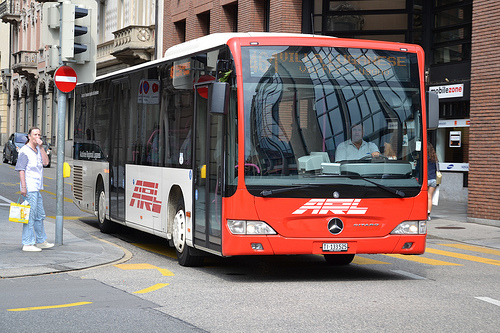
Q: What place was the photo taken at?
A: It was taken at the street.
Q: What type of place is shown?
A: It is a street.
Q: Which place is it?
A: It is a street.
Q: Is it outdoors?
A: Yes, it is outdoors.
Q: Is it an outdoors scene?
A: Yes, it is outdoors.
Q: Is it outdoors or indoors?
A: It is outdoors.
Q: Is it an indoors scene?
A: No, it is outdoors.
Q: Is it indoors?
A: No, it is outdoors.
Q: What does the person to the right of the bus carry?
A: The person carries a bag.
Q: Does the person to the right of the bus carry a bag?
A: Yes, the person carries a bag.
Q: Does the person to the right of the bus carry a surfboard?
A: No, the person carries a bag.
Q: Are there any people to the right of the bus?
A: Yes, there is a person to the right of the bus.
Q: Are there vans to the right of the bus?
A: No, there is a person to the right of the bus.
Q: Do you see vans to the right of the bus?
A: No, there is a person to the right of the bus.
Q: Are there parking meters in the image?
A: No, there are no parking meters.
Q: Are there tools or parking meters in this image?
A: No, there are no parking meters or tools.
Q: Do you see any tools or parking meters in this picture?
A: No, there are no parking meters or tools.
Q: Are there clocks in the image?
A: No, there are no clocks.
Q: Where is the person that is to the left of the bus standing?
A: The person is standing at the sidewalk.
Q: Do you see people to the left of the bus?
A: Yes, there is a person to the left of the bus.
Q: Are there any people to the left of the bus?
A: Yes, there is a person to the left of the bus.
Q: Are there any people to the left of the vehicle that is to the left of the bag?
A: Yes, there is a person to the left of the bus.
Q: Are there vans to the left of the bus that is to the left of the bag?
A: No, there is a person to the left of the bus.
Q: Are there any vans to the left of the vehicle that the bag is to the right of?
A: No, there is a person to the left of the bus.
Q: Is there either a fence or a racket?
A: No, there are no fences or rackets.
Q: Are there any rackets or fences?
A: No, there are no fences or rackets.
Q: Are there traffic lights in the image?
A: Yes, there is a traffic light.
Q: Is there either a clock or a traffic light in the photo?
A: Yes, there is a traffic light.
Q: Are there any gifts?
A: No, there are no gifts.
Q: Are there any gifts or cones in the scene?
A: No, there are no gifts or cones.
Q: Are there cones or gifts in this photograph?
A: No, there are no gifts or cones.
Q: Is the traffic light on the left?
A: Yes, the traffic light is on the left of the image.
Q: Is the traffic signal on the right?
A: No, the traffic signal is on the left of the image.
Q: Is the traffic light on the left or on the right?
A: The traffic light is on the left of the image.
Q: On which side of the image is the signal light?
A: The signal light is on the left of the image.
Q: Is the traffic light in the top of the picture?
A: Yes, the traffic light is in the top of the image.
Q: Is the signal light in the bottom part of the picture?
A: No, the signal light is in the top of the image.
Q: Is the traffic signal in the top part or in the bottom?
A: The traffic signal is in the top of the image.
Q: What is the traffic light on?
A: The traffic light is on the pole.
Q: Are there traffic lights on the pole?
A: Yes, there is a traffic light on the pole.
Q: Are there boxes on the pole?
A: No, there is a traffic light on the pole.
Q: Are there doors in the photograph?
A: Yes, there is a door.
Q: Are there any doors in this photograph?
A: Yes, there is a door.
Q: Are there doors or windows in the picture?
A: Yes, there is a door.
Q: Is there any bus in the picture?
A: Yes, there is a bus.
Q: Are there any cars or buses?
A: Yes, there is a bus.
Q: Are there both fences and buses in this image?
A: No, there is a bus but no fences.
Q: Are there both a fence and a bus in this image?
A: No, there is a bus but no fences.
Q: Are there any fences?
A: No, there are no fences.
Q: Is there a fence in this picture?
A: No, there are no fences.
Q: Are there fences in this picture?
A: No, there are no fences.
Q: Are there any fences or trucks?
A: No, there are no fences or trucks.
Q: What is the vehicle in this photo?
A: The vehicle is a bus.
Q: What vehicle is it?
A: The vehicle is a bus.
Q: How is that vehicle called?
A: This is a bus.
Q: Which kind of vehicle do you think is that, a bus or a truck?
A: This is a bus.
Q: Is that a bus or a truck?
A: That is a bus.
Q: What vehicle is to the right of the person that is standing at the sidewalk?
A: The vehicle is a bus.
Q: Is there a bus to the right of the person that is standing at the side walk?
A: Yes, there is a bus to the right of the person.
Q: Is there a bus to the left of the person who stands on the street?
A: No, the bus is to the right of the person.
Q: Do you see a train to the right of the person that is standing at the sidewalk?
A: No, there is a bus to the right of the person.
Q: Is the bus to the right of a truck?
A: No, the bus is to the right of a person.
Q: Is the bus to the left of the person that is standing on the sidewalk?
A: No, the bus is to the right of the person.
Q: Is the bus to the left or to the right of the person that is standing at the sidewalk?
A: The bus is to the right of the person.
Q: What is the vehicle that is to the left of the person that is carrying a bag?
A: The vehicle is a bus.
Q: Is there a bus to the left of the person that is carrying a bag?
A: Yes, there is a bus to the left of the person.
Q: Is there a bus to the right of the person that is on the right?
A: No, the bus is to the left of the person.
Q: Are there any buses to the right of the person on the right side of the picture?
A: No, the bus is to the left of the person.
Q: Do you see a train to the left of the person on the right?
A: No, there is a bus to the left of the person.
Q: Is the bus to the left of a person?
A: Yes, the bus is to the left of a person.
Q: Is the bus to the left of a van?
A: No, the bus is to the left of a person.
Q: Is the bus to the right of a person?
A: No, the bus is to the left of a person.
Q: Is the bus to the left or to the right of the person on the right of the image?
A: The bus is to the left of the person.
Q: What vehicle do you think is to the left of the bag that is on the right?
A: The vehicle is a bus.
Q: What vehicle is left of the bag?
A: The vehicle is a bus.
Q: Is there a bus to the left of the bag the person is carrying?
A: Yes, there is a bus to the left of the bag.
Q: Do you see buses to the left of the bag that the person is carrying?
A: Yes, there is a bus to the left of the bag.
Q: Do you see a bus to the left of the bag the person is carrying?
A: Yes, there is a bus to the left of the bag.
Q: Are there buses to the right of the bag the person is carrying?
A: No, the bus is to the left of the bag.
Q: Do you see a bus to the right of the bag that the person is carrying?
A: No, the bus is to the left of the bag.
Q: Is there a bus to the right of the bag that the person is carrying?
A: No, the bus is to the left of the bag.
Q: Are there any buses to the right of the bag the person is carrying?
A: No, the bus is to the left of the bag.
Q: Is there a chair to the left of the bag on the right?
A: No, there is a bus to the left of the bag.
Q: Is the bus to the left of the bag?
A: Yes, the bus is to the left of the bag.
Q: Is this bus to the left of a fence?
A: No, the bus is to the left of the bag.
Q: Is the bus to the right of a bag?
A: No, the bus is to the left of a bag.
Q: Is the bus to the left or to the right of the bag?
A: The bus is to the left of the bag.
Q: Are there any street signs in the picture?
A: Yes, there is a street sign.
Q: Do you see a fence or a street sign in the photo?
A: Yes, there is a street sign.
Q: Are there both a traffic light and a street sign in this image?
A: Yes, there are both a street sign and a traffic light.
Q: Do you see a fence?
A: No, there are no fences.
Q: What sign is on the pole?
A: The sign is a street sign.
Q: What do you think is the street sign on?
A: The street sign is on the pole.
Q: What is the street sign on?
A: The street sign is on the pole.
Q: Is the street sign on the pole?
A: Yes, the street sign is on the pole.